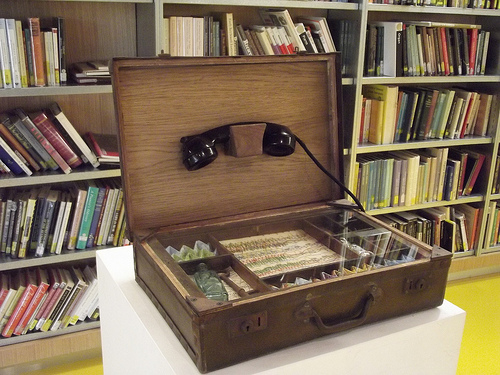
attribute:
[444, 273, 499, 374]
floor — yellow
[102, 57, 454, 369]
box — brown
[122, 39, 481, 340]
box — brown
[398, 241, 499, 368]
floor — yellow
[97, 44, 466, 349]
briefcase — brown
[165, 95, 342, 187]
telephone — old fashioned, black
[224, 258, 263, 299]
key — old